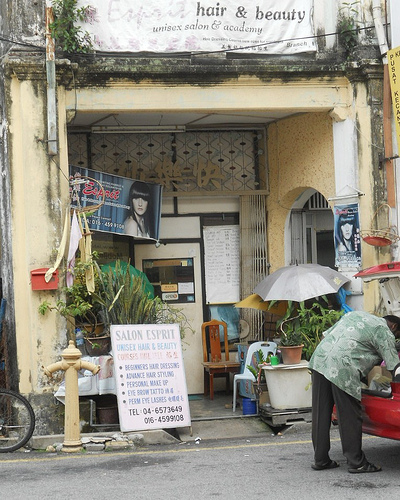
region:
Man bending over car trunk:
[311, 307, 399, 472]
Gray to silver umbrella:
[250, 260, 350, 304]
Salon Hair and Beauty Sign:
[109, 322, 193, 430]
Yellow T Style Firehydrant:
[42, 340, 102, 457]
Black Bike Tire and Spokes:
[0, 389, 36, 453]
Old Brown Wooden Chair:
[201, 319, 237, 399]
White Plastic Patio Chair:
[231, 338, 277, 412]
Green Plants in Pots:
[37, 260, 188, 351]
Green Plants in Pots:
[279, 307, 344, 364]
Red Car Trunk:
[324, 261, 399, 439]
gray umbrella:
[252, 257, 349, 303]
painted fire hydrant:
[40, 340, 101, 453]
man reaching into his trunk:
[304, 304, 397, 476]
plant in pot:
[273, 333, 303, 362]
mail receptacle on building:
[28, 268, 60, 292]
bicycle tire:
[0, 380, 36, 460]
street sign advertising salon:
[104, 320, 192, 432]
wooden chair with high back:
[197, 318, 238, 398]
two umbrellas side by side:
[222, 257, 350, 314]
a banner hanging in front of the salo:
[66, 175, 163, 249]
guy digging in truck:
[311, 255, 399, 480]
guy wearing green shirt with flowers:
[294, 300, 399, 473]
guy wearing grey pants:
[308, 304, 397, 474]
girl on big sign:
[68, 164, 168, 245]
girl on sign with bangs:
[69, 177, 169, 245]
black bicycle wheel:
[0, 378, 48, 458]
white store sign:
[96, 312, 216, 437]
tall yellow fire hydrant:
[42, 336, 102, 457]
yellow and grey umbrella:
[236, 250, 336, 315]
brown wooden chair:
[188, 311, 246, 396]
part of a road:
[290, 460, 300, 472]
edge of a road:
[119, 436, 128, 447]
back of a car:
[386, 407, 390, 411]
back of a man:
[326, 345, 337, 371]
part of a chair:
[211, 334, 217, 353]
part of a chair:
[231, 363, 242, 404]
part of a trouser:
[341, 415, 345, 449]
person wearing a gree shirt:
[311, 313, 383, 474]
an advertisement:
[111, 328, 188, 431]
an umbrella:
[258, 261, 350, 298]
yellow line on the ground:
[198, 439, 260, 451]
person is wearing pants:
[308, 396, 359, 465]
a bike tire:
[2, 388, 35, 453]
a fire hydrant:
[43, 343, 96, 460]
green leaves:
[290, 313, 321, 340]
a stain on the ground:
[73, 452, 174, 474]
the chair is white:
[247, 341, 274, 361]